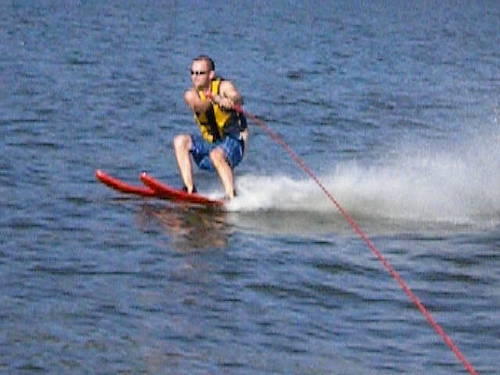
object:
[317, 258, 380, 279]
ripple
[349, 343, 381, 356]
ripple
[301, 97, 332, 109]
ripple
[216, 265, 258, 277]
ripple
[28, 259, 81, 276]
ripple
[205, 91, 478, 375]
rope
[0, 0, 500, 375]
water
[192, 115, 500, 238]
choppy water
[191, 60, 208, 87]
face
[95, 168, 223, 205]
red surfboard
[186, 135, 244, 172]
short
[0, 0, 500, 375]
lake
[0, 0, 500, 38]
skies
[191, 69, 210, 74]
sunglasses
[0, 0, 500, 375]
air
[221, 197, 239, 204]
ski boots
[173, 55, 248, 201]
man